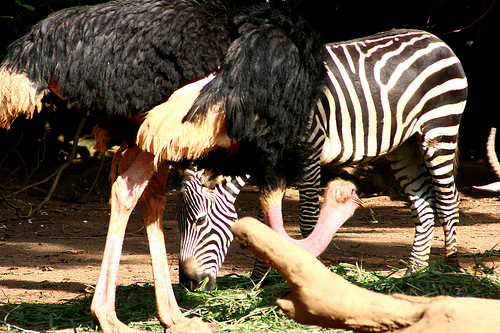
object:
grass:
[92, 280, 498, 331]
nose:
[356, 196, 361, 201]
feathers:
[6, 4, 327, 183]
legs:
[88, 149, 191, 323]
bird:
[0, 1, 370, 333]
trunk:
[227, 215, 423, 331]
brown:
[305, 273, 353, 304]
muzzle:
[179, 272, 218, 292]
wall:
[269, 92, 343, 137]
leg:
[294, 164, 320, 236]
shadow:
[20, 259, 70, 326]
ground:
[3, 195, 498, 331]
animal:
[174, 28, 467, 291]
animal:
[1, 4, 500, 332]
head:
[320, 179, 366, 210]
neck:
[261, 180, 328, 259]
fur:
[4, 72, 47, 126]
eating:
[175, 159, 242, 306]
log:
[282, 304, 415, 323]